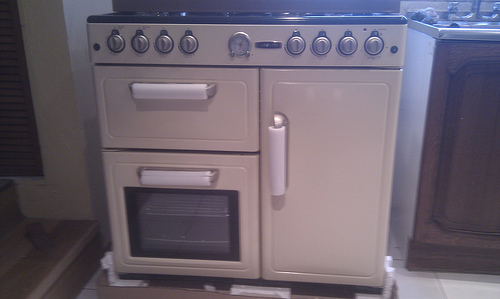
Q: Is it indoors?
A: Yes, it is indoors.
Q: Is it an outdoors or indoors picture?
A: It is indoors.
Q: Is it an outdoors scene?
A: No, it is indoors.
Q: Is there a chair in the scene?
A: No, there are no chairs.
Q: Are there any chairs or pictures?
A: No, there are no chairs or pictures.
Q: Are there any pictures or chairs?
A: No, there are no chairs or pictures.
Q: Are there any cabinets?
A: Yes, there is a cabinet.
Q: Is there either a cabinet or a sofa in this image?
A: Yes, there is a cabinet.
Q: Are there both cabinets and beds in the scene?
A: No, there is a cabinet but no beds.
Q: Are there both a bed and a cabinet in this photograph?
A: No, there is a cabinet but no beds.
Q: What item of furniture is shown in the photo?
A: The piece of furniture is a cabinet.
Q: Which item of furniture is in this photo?
A: The piece of furniture is a cabinet.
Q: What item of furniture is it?
A: The piece of furniture is a cabinet.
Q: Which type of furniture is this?
A: That is a cabinet.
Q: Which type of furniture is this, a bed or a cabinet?
A: That is a cabinet.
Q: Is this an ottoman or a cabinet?
A: This is a cabinet.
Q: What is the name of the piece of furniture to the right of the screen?
A: The piece of furniture is a cabinet.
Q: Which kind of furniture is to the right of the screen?
A: The piece of furniture is a cabinet.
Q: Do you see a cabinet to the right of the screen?
A: Yes, there is a cabinet to the right of the screen.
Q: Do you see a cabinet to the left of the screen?
A: No, the cabinet is to the right of the screen.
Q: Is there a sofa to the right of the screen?
A: No, there is a cabinet to the right of the screen.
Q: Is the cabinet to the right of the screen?
A: Yes, the cabinet is to the right of the screen.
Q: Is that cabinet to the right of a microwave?
A: No, the cabinet is to the right of the screen.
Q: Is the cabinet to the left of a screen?
A: No, the cabinet is to the right of a screen.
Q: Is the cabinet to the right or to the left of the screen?
A: The cabinet is to the right of the screen.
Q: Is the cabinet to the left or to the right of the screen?
A: The cabinet is to the right of the screen.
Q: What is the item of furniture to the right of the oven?
A: The piece of furniture is a cabinet.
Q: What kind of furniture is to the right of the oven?
A: The piece of furniture is a cabinet.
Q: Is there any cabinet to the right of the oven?
A: Yes, there is a cabinet to the right of the oven.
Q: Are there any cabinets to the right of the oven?
A: Yes, there is a cabinet to the right of the oven.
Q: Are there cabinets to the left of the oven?
A: No, the cabinet is to the right of the oven.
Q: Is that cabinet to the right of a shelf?
A: No, the cabinet is to the right of the oven.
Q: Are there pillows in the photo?
A: No, there are no pillows.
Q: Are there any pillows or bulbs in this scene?
A: No, there are no pillows or bulbs.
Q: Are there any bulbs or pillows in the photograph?
A: No, there are no pillows or bulbs.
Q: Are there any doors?
A: Yes, there is a door.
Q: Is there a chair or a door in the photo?
A: Yes, there is a door.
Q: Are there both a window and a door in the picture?
A: Yes, there are both a door and a window.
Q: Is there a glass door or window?
A: Yes, there is a glass door.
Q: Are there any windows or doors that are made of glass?
A: Yes, the door is made of glass.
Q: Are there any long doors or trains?
A: Yes, there is a long door.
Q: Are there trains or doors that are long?
A: Yes, the door is long.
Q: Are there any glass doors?
A: Yes, there is a door that is made of glass.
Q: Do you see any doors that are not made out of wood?
A: Yes, there is a door that is made of glass.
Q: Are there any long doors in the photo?
A: Yes, there is a long door.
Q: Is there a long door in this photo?
A: Yes, there is a long door.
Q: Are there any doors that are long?
A: Yes, there is a door that is long.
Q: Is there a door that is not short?
A: Yes, there is a long door.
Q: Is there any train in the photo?
A: No, there are no trains.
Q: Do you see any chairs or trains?
A: No, there are no trains or chairs.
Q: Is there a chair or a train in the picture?
A: No, there are no trains or chairs.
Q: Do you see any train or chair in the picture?
A: No, there are no trains or chairs.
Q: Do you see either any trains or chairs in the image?
A: No, there are no trains or chairs.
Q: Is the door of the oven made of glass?
A: Yes, the door is made of glass.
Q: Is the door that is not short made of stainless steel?
A: No, the door is made of glass.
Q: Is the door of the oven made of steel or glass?
A: The door is made of glass.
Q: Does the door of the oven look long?
A: Yes, the door is long.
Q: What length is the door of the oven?
A: The door is long.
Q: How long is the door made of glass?
A: The door is long.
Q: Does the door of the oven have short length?
A: No, the door is long.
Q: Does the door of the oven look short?
A: No, the door is long.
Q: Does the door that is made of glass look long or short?
A: The door is long.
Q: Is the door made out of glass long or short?
A: The door is long.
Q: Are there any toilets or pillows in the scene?
A: No, there are no pillows or toilets.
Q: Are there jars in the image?
A: No, there are no jars.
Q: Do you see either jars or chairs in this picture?
A: No, there are no jars or chairs.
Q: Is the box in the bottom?
A: Yes, the box is in the bottom of the image.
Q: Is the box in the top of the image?
A: No, the box is in the bottom of the image.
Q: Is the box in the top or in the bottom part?
A: The box is in the bottom of the image.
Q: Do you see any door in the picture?
A: Yes, there are doors.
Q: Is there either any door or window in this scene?
A: Yes, there are doors.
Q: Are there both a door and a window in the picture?
A: Yes, there are both a door and a window.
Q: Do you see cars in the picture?
A: No, there are no cars.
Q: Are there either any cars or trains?
A: No, there are no cars or trains.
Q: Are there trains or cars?
A: No, there are no cars or trains.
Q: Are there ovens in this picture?
A: Yes, there is an oven.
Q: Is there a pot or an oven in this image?
A: Yes, there is an oven.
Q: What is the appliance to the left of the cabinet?
A: The appliance is an oven.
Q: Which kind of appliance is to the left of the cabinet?
A: The appliance is an oven.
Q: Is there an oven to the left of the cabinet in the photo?
A: Yes, there is an oven to the left of the cabinet.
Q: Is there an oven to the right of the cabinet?
A: No, the oven is to the left of the cabinet.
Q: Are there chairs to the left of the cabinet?
A: No, there is an oven to the left of the cabinet.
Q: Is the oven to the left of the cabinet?
A: Yes, the oven is to the left of the cabinet.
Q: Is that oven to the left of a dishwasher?
A: No, the oven is to the left of the cabinet.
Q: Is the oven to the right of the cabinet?
A: No, the oven is to the left of the cabinet.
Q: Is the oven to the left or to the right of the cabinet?
A: The oven is to the left of the cabinet.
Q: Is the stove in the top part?
A: Yes, the stove is in the top of the image.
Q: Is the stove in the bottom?
A: No, the stove is in the top of the image.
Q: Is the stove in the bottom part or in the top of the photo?
A: The stove is in the top of the image.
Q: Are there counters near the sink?
A: No, there is a stove near the sink.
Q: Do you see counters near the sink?
A: No, there is a stove near the sink.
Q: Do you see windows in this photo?
A: Yes, there is a window.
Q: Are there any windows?
A: Yes, there is a window.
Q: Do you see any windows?
A: Yes, there is a window.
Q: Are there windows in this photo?
A: Yes, there is a window.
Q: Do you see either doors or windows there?
A: Yes, there is a window.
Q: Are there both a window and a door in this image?
A: Yes, there are both a window and a door.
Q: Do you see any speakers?
A: No, there are no speakers.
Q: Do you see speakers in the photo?
A: No, there are no speakers.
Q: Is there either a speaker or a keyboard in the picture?
A: No, there are no speakers or keyboards.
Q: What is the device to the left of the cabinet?
A: The device is a screen.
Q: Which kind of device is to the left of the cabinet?
A: The device is a screen.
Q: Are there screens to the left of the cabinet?
A: Yes, there is a screen to the left of the cabinet.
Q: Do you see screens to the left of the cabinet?
A: Yes, there is a screen to the left of the cabinet.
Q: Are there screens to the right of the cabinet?
A: No, the screen is to the left of the cabinet.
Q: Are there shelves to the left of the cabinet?
A: No, there is a screen to the left of the cabinet.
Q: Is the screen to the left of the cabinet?
A: Yes, the screen is to the left of the cabinet.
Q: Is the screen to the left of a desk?
A: No, the screen is to the left of the cabinet.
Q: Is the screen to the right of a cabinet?
A: No, the screen is to the left of a cabinet.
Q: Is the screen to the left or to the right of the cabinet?
A: The screen is to the left of the cabinet.